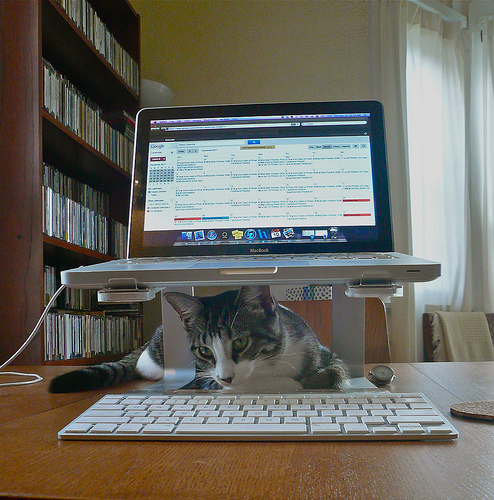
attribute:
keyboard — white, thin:
[57, 393, 458, 440]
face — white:
[361, 358, 399, 389]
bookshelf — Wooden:
[1, 2, 143, 367]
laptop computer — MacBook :
[60, 91, 443, 290]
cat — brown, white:
[46, 281, 354, 395]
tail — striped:
[44, 338, 155, 395]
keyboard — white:
[56, 389, 465, 444]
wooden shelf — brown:
[0, 1, 143, 368]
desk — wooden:
[0, 358, 493, 498]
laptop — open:
[62, 94, 448, 326]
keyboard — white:
[103, 201, 453, 431]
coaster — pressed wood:
[437, 390, 492, 435]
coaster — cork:
[446, 398, 492, 418]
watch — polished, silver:
[360, 357, 403, 383]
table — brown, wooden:
[0, 361, 491, 497]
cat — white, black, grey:
[52, 292, 417, 433]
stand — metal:
[96, 268, 407, 391]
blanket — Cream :
[419, 305, 491, 368]